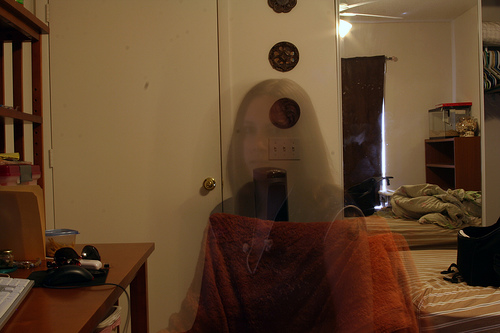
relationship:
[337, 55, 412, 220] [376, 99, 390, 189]
curtains on window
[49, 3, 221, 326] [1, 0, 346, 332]
door on wall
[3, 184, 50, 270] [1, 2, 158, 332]
file on desk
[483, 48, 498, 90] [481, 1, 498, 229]
hangers in closet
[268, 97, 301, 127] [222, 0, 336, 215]
circle on wall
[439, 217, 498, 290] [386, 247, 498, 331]
bag on bed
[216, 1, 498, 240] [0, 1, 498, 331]
mirror on a wall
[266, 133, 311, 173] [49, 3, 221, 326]
light switch near door